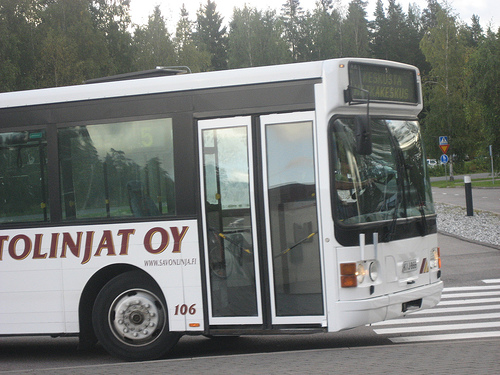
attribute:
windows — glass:
[22, 134, 290, 224]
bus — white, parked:
[2, 45, 452, 365]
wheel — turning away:
[94, 269, 169, 356]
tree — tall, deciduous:
[365, 0, 437, 82]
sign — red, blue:
[433, 134, 450, 166]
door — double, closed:
[194, 110, 327, 334]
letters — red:
[0, 224, 189, 264]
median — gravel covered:
[433, 201, 499, 251]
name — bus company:
[1, 225, 188, 265]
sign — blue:
[434, 133, 449, 149]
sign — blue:
[436, 152, 453, 168]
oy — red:
[141, 219, 191, 257]